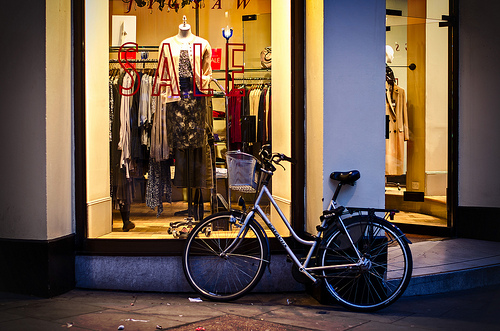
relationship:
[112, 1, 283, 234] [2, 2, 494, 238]
window of store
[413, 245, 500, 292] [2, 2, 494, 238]
step in front of store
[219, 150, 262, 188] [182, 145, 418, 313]
basket on bicycle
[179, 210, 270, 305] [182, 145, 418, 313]
wheel on bicycle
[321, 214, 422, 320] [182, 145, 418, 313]
wheel on bicycle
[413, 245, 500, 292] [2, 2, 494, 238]
step on store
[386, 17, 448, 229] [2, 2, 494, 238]
door of store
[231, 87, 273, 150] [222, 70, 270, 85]
clothing on rack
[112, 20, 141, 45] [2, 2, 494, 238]
vase in store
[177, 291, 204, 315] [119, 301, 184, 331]
trash on ground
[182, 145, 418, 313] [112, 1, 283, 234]
bicycle in front of window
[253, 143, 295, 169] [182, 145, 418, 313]
handlebars on bike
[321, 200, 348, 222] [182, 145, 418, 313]
rack on bicycle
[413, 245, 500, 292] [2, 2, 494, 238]
step to store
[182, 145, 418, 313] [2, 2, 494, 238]
bicycle in front of store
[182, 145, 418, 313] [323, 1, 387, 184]
bicycle on wall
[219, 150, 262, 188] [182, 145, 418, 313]
basket on bike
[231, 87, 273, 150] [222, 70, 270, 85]
clothes on rack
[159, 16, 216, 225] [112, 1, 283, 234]
mannequin in window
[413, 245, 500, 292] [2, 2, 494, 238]
step of store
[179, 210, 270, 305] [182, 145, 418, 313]
tire on bike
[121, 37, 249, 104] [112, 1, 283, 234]
sale on window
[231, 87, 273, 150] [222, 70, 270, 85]
clothes hanging on rack